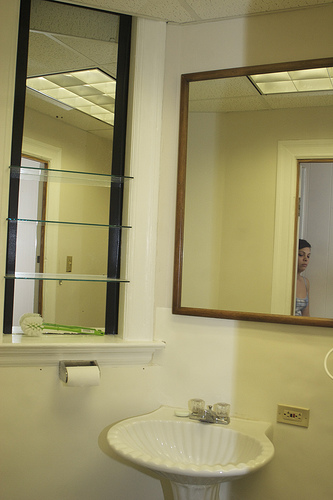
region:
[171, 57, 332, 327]
Brown framed mirror in bathroom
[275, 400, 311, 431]
White electric outlet in bathroom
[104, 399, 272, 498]
White bathroom sink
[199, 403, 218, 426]
Silver faucet in bathroom sink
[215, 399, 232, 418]
Clear faucet handle on bathroom sink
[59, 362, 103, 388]
White toilet paper roll hanging in bathroom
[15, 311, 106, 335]
Green handled bathroom brush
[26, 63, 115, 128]
Overhead light next to bathroom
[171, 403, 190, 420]
White soap on bathroom sink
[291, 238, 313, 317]
Lady's image reflected in bathroom mirror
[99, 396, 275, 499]
white pedestal style sink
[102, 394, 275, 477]
sink with scalloped bowl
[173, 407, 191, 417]
soap next to faucets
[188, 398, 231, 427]
faucets on sink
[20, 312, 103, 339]
green handled toilet brush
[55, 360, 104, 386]
toilet paper dispenser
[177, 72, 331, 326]
large mirror with brown frame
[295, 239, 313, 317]
young woman's reflection in mirror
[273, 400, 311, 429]
electrical outlet next to sink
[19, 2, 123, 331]
tall mirror with glass shelves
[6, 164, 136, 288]
Window panes on the window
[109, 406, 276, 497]
A pedestal sink in the bathroom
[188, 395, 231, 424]
Two silver faucets on the sink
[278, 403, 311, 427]
A cream double socket on wall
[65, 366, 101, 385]
A roll of white tissue on holder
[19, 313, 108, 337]
A green toilet brush on window sill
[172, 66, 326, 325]
A large bathroom mirror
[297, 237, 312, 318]
A woman's reflection on the mirror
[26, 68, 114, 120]
A square light on the ceiling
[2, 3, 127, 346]
A rectangular window in bathroom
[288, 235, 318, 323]
a reflection of a women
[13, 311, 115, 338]
a green toilet brush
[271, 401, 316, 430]
an electric outet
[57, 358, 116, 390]
toilet paper on a holder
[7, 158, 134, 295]
bathroom shelving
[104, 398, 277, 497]
a bathroom sink and faucet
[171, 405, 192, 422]
soap sitting on a bathroom sink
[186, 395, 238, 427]
a sink faucet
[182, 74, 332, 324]
mirror with reflection of a woman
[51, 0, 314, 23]
bathroom cieling panels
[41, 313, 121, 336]
the handle is green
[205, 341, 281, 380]
the wall is beige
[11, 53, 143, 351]
the boarder is black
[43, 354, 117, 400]
the tissue is white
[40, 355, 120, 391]
the tissue is on the wall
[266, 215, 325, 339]
a girl on the mirror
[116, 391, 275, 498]
the sink is white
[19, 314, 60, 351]
the bristles are white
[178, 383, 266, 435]
the faucet is close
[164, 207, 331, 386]
the mirror is on the wall